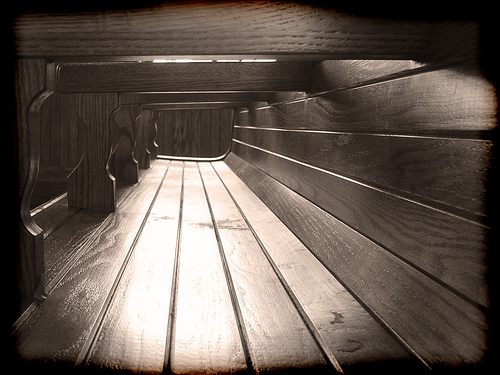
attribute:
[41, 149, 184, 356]
plank — horizontal, wood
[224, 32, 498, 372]
planks — wood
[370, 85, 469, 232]
wood — brown, dark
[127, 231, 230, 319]
wood — dark, brown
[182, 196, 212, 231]
grain — dark, brown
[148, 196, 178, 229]
grain — dark, brown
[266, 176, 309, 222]
grain — dark, brown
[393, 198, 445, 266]
grain — dark, brown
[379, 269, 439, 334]
grain — dark, brown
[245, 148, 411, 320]
wood grain — brown, dark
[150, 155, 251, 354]
photographer — wood, vertical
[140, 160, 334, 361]
wood — structured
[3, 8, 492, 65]
wood — plank, horizontal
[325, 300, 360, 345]
mark — seal shaped, small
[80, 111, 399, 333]
planks — flat, wood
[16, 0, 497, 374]
bench — wood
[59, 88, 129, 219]
plank — vertical, wood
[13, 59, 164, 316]
wood planks — vertical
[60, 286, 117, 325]
wood — brown, dark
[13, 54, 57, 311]
plank — vertical, wood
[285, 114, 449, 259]
wood — patterned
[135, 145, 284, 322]
wood — patterned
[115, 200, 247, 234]
mark — large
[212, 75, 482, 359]
planks — wood, horizontal